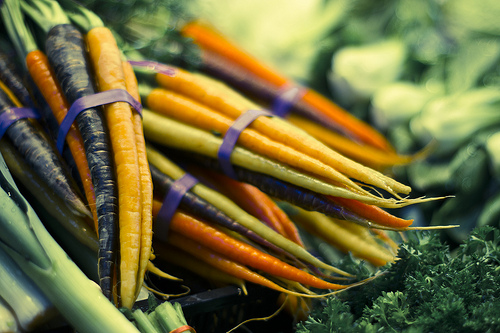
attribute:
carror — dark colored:
[125, 20, 372, 150]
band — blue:
[262, 79, 299, 113]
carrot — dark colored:
[92, 30, 139, 285]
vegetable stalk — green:
[0, 167, 135, 329]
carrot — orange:
[157, 25, 389, 252]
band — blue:
[203, 95, 275, 163]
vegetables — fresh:
[14, 5, 422, 317]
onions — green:
[20, 247, 97, 322]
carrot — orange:
[150, 87, 229, 123]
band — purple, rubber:
[218, 108, 272, 183]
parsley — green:
[294, 220, 496, 330]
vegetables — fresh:
[0, 0, 499, 332]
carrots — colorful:
[31, 53, 91, 134]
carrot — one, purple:
[34, 46, 205, 308]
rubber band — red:
[271, 86, 301, 115]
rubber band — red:
[214, 107, 274, 162]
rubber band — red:
[154, 170, 198, 237]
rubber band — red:
[51, 87, 143, 154]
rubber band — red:
[0, 105, 45, 130]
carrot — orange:
[130, 23, 416, 297]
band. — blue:
[225, 123, 237, 146]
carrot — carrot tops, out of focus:
[171, 18, 402, 159]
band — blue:
[49, 93, 142, 119]